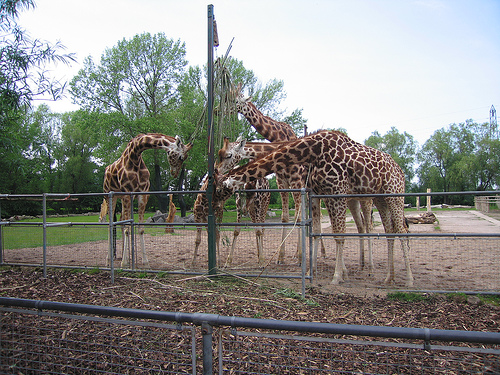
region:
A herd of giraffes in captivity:
[94, 48, 421, 299]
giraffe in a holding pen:
[95, 127, 192, 272]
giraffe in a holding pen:
[177, 133, 261, 268]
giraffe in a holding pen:
[209, 79, 319, 276]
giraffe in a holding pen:
[219, 123, 417, 295]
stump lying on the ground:
[394, 207, 440, 235]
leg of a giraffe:
[327, 189, 353, 292]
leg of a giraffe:
[212, 198, 247, 274]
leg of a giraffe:
[181, 213, 208, 275]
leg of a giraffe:
[271, 174, 290, 271]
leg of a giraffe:
[378, 184, 424, 294]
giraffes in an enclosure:
[79, 83, 452, 308]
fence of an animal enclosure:
[8, 281, 498, 372]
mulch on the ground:
[74, 289, 254, 358]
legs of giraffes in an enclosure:
[256, 213, 444, 305]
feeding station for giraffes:
[205, 50, 240, 130]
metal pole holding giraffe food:
[187, 9, 244, 276]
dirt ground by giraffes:
[418, 234, 490, 286]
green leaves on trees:
[79, 66, 204, 124]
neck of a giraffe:
[241, 99, 293, 141]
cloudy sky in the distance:
[318, 64, 473, 117]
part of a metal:
[331, 333, 353, 355]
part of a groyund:
[356, 308, 364, 320]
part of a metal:
[300, 325, 310, 333]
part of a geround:
[288, 301, 302, 318]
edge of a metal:
[364, 223, 391, 245]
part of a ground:
[363, 301, 369, 316]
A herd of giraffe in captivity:
[91, 25, 435, 300]